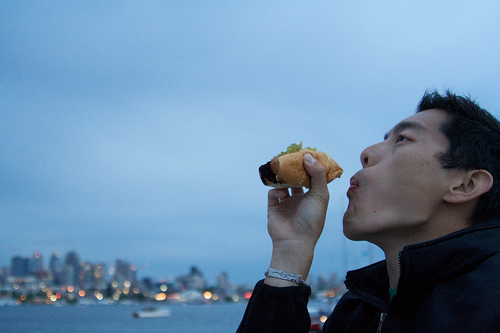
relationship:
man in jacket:
[201, 80, 493, 325] [222, 219, 483, 331]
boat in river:
[134, 307, 174, 318] [0, 303, 248, 333]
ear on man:
[430, 159, 493, 222] [201, 80, 493, 325]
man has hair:
[201, 80, 493, 325] [408, 73, 498, 187]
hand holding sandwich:
[266, 153, 330, 241] [242, 133, 343, 196]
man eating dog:
[201, 80, 493, 325] [235, 142, 362, 196]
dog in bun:
[235, 142, 362, 196] [264, 142, 360, 194]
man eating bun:
[201, 80, 493, 325] [258, 140, 343, 188]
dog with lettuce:
[271, 159, 336, 184] [272, 131, 326, 163]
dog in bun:
[271, 159, 336, 184] [248, 133, 349, 191]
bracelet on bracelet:
[264, 268, 309, 287] [264, 268, 309, 287]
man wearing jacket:
[237, 88, 500, 333] [233, 223, 500, 333]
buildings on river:
[3, 248, 346, 305] [4, 300, 246, 330]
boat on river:
[134, 306, 174, 318] [0, 295, 337, 329]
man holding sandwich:
[237, 88, 500, 333] [257, 139, 344, 187]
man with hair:
[237, 88, 500, 333] [413, 87, 495, 225]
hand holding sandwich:
[264, 153, 332, 267] [256, 142, 343, 188]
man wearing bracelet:
[237, 88, 500, 333] [260, 265, 308, 285]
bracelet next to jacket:
[264, 266, 303, 287] [237, 225, 498, 328]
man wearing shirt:
[237, 88, 500, 333] [388, 290, 398, 299]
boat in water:
[134, 307, 174, 318] [0, 294, 337, 331]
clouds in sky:
[83, 108, 219, 224] [2, 0, 495, 285]